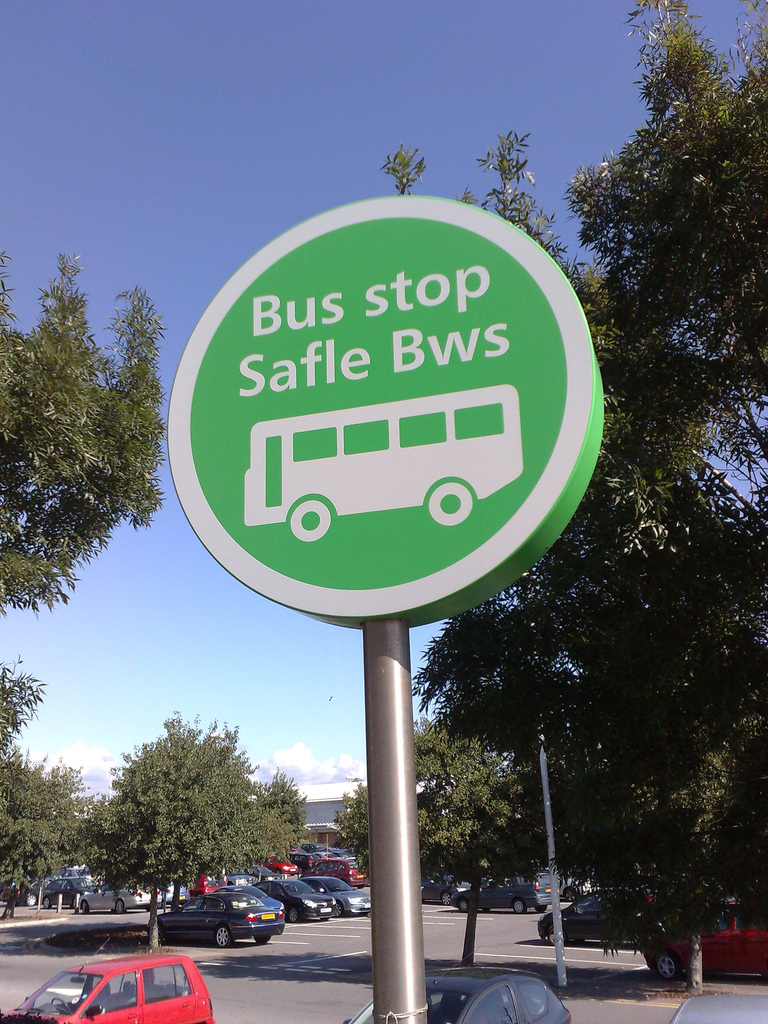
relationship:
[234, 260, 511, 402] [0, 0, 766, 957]
white letters on green background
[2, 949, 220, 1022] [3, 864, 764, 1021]
vehicle in lot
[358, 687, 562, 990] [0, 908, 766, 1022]
tree on parking lot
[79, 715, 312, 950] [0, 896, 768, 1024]
tree on side of lot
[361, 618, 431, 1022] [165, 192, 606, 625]
metal pole with sign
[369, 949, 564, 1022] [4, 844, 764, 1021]
car parked in lot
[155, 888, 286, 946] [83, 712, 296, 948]
car parked under tree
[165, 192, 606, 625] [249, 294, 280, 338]
sign has letter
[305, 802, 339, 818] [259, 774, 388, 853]
wall on side building